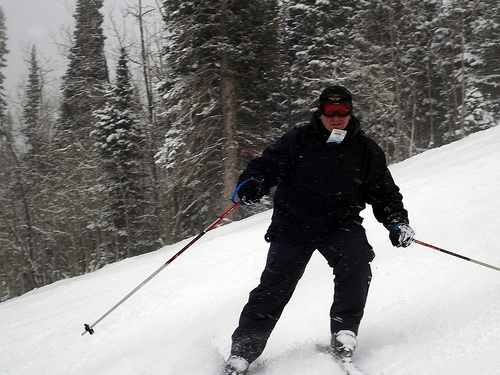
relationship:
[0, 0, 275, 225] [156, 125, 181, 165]
trees covered with snow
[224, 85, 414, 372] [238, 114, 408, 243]
man has black coat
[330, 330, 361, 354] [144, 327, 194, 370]
shoe covered with snow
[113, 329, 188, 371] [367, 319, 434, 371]
snow on ground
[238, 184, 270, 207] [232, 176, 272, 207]
glove on hand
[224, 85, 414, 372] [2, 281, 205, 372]
man skiing on snow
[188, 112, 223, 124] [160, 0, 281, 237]
branch on tree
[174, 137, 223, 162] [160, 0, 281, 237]
branch on tree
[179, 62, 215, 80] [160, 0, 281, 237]
branch on tree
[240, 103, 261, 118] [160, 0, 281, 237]
branch on tree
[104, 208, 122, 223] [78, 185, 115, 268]
branch on tree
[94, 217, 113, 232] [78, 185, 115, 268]
branch on tree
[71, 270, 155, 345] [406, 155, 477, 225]
pole in snow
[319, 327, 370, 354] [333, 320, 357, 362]
shoe on foot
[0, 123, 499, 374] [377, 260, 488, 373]
snow on ground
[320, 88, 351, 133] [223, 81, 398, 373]
face of man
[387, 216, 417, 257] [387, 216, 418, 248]
glove on hand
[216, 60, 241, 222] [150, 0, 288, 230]
trunk of tall tree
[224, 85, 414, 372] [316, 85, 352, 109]
man has black hat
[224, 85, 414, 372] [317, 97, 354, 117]
man has goggles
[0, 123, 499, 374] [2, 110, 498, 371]
snow on hill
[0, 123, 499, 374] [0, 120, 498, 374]
snow on grownd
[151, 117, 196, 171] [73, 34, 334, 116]
snow on a trees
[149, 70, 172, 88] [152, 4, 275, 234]
snow on a trees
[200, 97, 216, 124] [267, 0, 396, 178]
snow on a trees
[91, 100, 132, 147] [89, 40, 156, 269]
snow on a trees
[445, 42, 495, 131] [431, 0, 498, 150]
snow on a trees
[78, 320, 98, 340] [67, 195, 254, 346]
bottom on a pole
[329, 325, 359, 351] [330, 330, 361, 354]
snow on a shoe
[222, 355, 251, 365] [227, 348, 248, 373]
snow on a boot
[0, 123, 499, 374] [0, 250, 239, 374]
snow on ground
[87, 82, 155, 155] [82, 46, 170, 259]
snow on tall tree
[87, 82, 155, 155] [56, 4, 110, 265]
snow on tall tree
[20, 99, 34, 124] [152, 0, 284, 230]
snow on tall tree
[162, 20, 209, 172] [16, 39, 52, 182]
snow on tall tree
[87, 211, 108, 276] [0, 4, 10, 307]
snow on tall tree